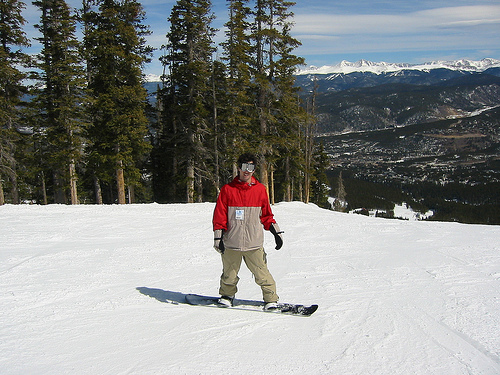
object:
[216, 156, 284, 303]
man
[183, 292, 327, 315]
snowboard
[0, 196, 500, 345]
hill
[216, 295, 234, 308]
feet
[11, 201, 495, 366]
ground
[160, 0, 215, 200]
trees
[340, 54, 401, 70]
mountains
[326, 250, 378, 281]
snow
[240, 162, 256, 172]
goggles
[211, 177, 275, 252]
jacket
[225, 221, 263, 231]
waist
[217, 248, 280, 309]
pants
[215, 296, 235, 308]
straps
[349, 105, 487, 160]
slants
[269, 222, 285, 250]
gloves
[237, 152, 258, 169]
hair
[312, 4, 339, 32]
back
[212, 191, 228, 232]
sleeve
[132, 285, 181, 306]
shadow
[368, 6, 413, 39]
clouds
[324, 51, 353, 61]
sky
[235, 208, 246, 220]
lift ticket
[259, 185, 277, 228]
arm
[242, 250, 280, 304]
legs